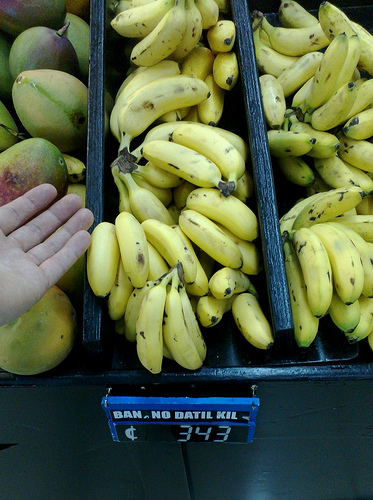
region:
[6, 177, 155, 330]
Hand by the fruit.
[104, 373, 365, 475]
Price of the fruits.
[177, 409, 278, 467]
The numbers three four three.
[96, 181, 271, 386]
Bananas in a bin.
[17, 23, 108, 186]
Other fruit by the bananas.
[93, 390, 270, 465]
White lettering on the price sign.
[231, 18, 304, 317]
Wood seperator on the bins.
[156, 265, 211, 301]
Stem of the bananas.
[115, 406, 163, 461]
Price sign on the blue sign.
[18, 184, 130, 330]
A human hand.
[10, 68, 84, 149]
green mango near bananas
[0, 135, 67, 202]
red and green mango next to mango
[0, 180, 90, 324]
caucassian hand over mangos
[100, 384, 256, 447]
blue, black and white sign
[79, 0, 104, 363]
dark colored wooden divider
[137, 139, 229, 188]
bright yellow banana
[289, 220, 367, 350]
bright yellow bunch of bananas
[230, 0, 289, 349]
painted wooden divider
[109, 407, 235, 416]
white text on sign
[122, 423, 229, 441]
price on sign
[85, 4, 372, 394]
Small bananas in a container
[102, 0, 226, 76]
Handle of bananas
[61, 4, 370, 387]
Container is black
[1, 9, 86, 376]
Mangoes on side of container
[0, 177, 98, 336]
Hand is palm up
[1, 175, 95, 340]
Hand shows four fingers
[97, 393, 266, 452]
Sign display price of bananas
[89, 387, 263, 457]
Sign has blue frame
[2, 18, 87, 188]
Mangoes are green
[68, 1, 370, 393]
Bananas container is black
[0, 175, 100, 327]
an open palmed hand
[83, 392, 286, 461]
a blue price sign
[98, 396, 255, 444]
white writing on black background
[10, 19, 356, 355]
a small fruit stand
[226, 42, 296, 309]
a wooden barrier on stand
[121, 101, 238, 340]
piles of yellow fruit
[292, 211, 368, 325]
some ripe yellow bananas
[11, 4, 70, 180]
a few mangoes together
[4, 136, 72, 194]
a red and green fruit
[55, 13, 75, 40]
a small fruit stem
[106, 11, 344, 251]
A bunch of yellow bananas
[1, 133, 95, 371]
A hand above mangoes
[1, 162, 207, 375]
A hand next to a bunch of bananas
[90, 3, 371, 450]
Yellow bananas for sale on display.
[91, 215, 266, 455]
Sign displaying price for bananas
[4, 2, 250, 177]
Bananas displayed next to bananas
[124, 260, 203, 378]
Bunch of yellow bananas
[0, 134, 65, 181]
Red and green mango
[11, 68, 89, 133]
Green mango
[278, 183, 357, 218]
Banana with black spots